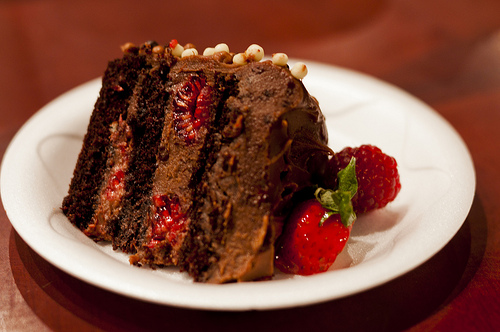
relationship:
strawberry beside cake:
[279, 155, 357, 275] [62, 39, 335, 284]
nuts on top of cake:
[119, 37, 307, 82] [62, 39, 335, 284]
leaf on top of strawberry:
[312, 156, 359, 227] [279, 155, 357, 275]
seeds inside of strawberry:
[288, 231, 329, 271] [279, 155, 357, 275]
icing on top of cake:
[208, 60, 328, 281] [62, 39, 335, 284]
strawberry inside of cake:
[172, 75, 210, 143] [62, 39, 335, 284]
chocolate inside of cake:
[145, 59, 220, 265] [62, 39, 335, 284]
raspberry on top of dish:
[328, 144, 402, 215] [1, 51, 478, 310]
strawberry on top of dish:
[279, 155, 357, 275] [1, 51, 478, 310]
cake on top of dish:
[62, 39, 335, 284] [1, 51, 478, 310]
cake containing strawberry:
[62, 39, 335, 284] [279, 155, 357, 275]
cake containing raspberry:
[62, 39, 335, 284] [328, 144, 402, 215]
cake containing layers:
[62, 39, 335, 284] [146, 62, 222, 262]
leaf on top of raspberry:
[312, 156, 359, 227] [328, 144, 402, 215]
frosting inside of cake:
[92, 119, 134, 238] [62, 39, 335, 284]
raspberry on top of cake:
[324, 144, 401, 217] [62, 39, 335, 284]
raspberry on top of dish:
[324, 144, 401, 217] [1, 51, 478, 310]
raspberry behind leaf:
[328, 144, 402, 215] [312, 156, 359, 227]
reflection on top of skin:
[296, 208, 311, 242] [275, 198, 348, 274]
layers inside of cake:
[146, 62, 222, 262] [62, 39, 335, 284]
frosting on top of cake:
[201, 64, 327, 285] [62, 39, 335, 284]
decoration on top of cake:
[123, 37, 308, 80] [62, 39, 335, 284]